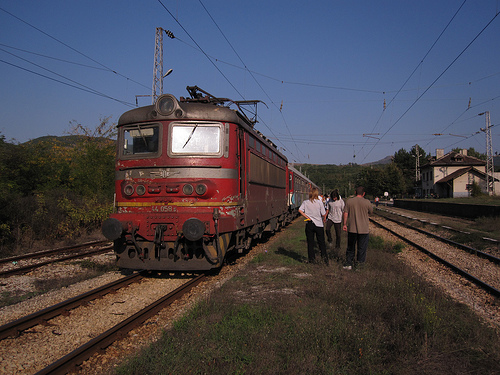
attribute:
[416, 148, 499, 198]
building — brown and white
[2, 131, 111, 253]
hill — grassy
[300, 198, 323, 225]
shirt — white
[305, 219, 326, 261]
pants — black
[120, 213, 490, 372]
grass — green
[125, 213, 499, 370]
foliage — green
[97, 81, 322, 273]
train — red, long, old, rusty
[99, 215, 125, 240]
bumper — black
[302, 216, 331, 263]
pants — black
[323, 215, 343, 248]
pants — black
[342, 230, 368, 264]
pants — black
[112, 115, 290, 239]
surface — weathered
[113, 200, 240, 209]
stripe — yellow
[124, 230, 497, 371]
grass — green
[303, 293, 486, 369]
foliage — green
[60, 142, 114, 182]
grass — green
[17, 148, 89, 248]
foliage — green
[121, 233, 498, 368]
foliage — green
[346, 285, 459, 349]
grass — green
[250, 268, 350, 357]
grass — green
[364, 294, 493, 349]
foliage — green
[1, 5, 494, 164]
sky — blue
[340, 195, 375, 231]
shirt — tan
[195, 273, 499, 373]
grass — green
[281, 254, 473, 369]
foliage — green